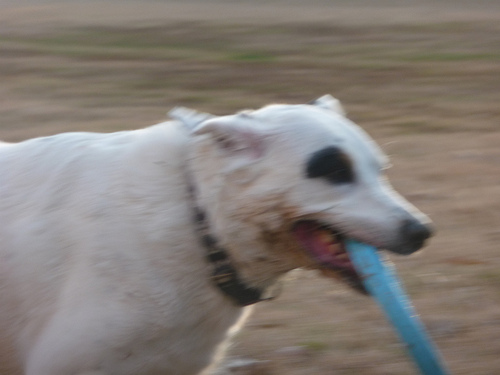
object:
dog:
[0, 93, 433, 375]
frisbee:
[348, 238, 458, 374]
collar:
[184, 163, 259, 307]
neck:
[173, 212, 297, 304]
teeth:
[297, 219, 363, 269]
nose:
[403, 213, 438, 249]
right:
[194, 151, 283, 225]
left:
[303, 98, 365, 113]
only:
[0, 209, 209, 375]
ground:
[294, 33, 493, 89]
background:
[0, 0, 499, 374]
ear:
[189, 111, 265, 155]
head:
[185, 95, 434, 300]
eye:
[301, 143, 355, 191]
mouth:
[292, 205, 442, 305]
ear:
[310, 89, 356, 115]